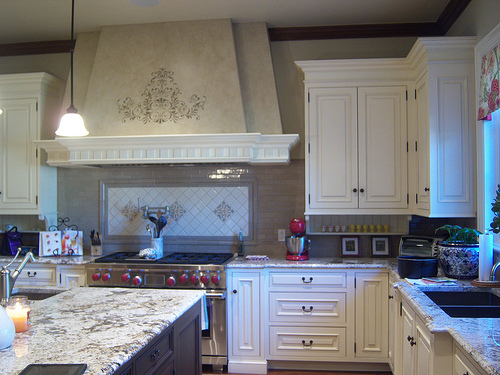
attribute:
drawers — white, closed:
[234, 262, 351, 362]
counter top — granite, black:
[6, 282, 206, 373]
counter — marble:
[6, 270, 211, 367]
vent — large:
[28, 8, 309, 175]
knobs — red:
[209, 270, 221, 288]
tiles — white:
[99, 181, 255, 242]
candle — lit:
[4, 290, 34, 339]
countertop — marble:
[1, 285, 205, 370]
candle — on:
[2, 289, 38, 334]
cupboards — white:
[299, 63, 476, 215]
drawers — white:
[232, 241, 377, 371]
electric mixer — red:
[283, 218, 311, 260]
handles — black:
[301, 275, 314, 285]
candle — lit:
[5, 293, 32, 332]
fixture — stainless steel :
[102, 204, 203, 255]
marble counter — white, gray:
[68, 282, 203, 360]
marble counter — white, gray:
[440, 312, 492, 372]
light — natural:
[449, 117, 497, 274]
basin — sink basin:
[425, 289, 498, 314]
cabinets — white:
[219, 257, 409, 372]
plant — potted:
[431, 200, 482, 300]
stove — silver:
[113, 216, 260, 292]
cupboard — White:
[224, 269, 266, 365]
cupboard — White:
[352, 267, 389, 361]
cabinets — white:
[2, 25, 498, 372]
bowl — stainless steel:
[287, 234, 311, 253]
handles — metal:
[302, 303, 313, 313]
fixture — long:
[55, 0, 91, 137]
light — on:
[53, 111, 91, 136]